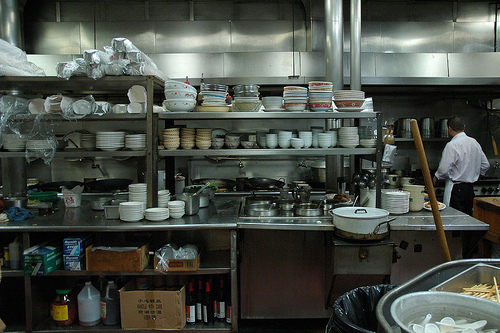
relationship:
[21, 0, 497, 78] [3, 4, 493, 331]
air`s ducts in a kitchen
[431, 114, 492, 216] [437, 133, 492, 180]
person wears white outfit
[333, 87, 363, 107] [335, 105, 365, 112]
bowls on plate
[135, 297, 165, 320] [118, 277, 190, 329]
lettering on box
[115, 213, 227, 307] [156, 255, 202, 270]
plastic cups in box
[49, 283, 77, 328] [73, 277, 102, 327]
jar by bottles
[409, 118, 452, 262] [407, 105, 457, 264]
pole on mop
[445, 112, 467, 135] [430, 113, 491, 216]
head on man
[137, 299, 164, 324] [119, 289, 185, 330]
writing on box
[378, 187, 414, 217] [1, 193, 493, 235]
plates on countertop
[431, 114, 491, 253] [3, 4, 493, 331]
person in kitchen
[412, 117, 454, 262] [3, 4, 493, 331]
pole in kitchen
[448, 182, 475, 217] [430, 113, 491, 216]
pants on man